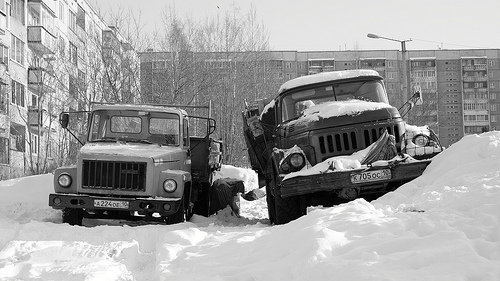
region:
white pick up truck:
[46, 98, 242, 228]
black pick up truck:
[240, 63, 445, 226]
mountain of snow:
[274, 123, 494, 280]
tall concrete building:
[140, 40, 498, 178]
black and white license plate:
[86, 195, 136, 212]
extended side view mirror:
[57, 105, 93, 148]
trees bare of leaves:
[160, 17, 273, 100]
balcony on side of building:
[26, 21, 62, 55]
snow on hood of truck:
[292, 97, 394, 130]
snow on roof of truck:
[267, 63, 379, 90]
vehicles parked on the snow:
[29, 6, 498, 265]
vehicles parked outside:
[30, 52, 497, 236]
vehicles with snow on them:
[27, 9, 494, 271]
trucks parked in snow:
[17, 47, 437, 277]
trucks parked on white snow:
[47, 52, 462, 193]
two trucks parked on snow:
[5, 25, 483, 280]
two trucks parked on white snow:
[61, 46, 426, 262]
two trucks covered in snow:
[52, 62, 440, 212]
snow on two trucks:
[57, 56, 496, 264]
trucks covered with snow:
[24, 20, 474, 278]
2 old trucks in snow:
[28, 34, 441, 209]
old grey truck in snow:
[49, 84, 252, 242]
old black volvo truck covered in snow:
[236, 46, 450, 221]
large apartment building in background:
[128, 41, 497, 200]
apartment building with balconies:
[2, 0, 150, 203]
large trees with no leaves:
[24, 3, 323, 172]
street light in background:
[358, 8, 450, 164]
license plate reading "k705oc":
[318, 153, 431, 192]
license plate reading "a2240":
[85, 193, 147, 216]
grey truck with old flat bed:
[61, 88, 258, 249]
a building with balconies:
[113, 49, 498, 156]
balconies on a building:
[138, 30, 498, 133]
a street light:
[350, 17, 442, 125]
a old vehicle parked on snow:
[221, 52, 458, 262]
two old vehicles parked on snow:
[39, 67, 442, 216]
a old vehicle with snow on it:
[230, 63, 465, 207]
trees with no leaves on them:
[73, 11, 311, 158]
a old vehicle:
[36, 84, 243, 236]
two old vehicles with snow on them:
[51, 75, 474, 250]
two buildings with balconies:
[13, 5, 334, 156]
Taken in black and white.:
[0, 2, 499, 265]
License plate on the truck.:
[345, 166, 405, 193]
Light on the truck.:
[266, 149, 321, 186]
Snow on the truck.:
[272, 60, 372, 101]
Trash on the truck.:
[357, 130, 404, 167]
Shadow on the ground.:
[34, 224, 143, 263]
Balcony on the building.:
[13, 11, 77, 65]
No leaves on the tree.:
[130, 28, 263, 97]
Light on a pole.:
[355, 21, 433, 66]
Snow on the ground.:
[234, 205, 403, 275]